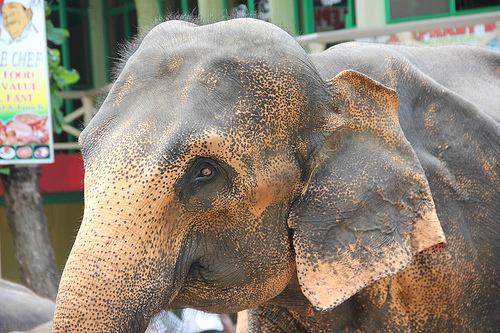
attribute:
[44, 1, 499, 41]
trim — green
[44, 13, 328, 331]
head — yellow, gray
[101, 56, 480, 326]
elephant — grey, patchy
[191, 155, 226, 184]
eye — yellow 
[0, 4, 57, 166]
sign — white , red, yellow, green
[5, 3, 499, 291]
building — green, white, red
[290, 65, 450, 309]
elephant ear — yellow , gray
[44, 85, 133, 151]
railing — white 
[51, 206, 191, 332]
trunk — gray, yellow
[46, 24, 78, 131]
leaves — green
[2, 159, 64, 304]
tree — slender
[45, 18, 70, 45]
leaves — green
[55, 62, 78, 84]
leaves — green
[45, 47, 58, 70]
leaves — green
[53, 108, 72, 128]
leaves — green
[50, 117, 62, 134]
leaves — green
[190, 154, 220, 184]
eye — spotted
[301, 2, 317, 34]
frame — green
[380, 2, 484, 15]
frame — green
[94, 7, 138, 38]
frame — green